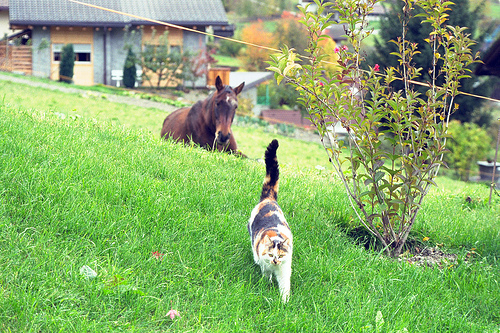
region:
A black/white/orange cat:
[245, 135, 300, 305]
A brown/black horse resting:
[155, 75, 250, 160]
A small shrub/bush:
[297, 30, 472, 260]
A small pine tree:
[115, 42, 140, 83]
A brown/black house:
[6, 0, 232, 85]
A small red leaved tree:
[182, 31, 212, 81]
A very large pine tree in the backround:
[351, 1, 496, 122]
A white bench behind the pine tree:
[107, 65, 138, 85]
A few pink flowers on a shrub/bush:
[330, 40, 385, 86]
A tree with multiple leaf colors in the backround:
[240, 10, 343, 78]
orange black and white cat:
[237, 123, 314, 295]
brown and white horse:
[156, 70, 260, 169]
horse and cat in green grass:
[138, 43, 303, 305]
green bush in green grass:
[300, 8, 460, 266]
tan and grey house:
[15, 5, 231, 98]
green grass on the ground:
[36, 165, 201, 315]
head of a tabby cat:
[256, 215, 297, 275]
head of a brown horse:
[205, 61, 251, 141]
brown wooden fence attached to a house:
[1, 40, 41, 86]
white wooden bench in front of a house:
[95, 55, 160, 96]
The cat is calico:
[231, 179, 306, 279]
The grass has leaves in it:
[46, 220, 148, 308]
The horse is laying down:
[165, 79, 280, 148]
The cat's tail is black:
[249, 135, 292, 199]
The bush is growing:
[305, 199, 442, 282]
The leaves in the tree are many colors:
[234, 15, 342, 95]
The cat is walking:
[239, 221, 311, 306]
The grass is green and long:
[48, 294, 110, 331]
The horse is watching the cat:
[195, 68, 255, 161]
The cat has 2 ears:
[251, 232, 295, 254]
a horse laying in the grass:
[160, 74, 247, 160]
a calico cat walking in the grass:
[249, 138, 292, 306]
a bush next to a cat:
[306, 0, 471, 246]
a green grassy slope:
[0, 80, 497, 326]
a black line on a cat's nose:
[270, 252, 276, 262]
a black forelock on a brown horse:
[216, 81, 228, 92]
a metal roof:
[5, 0, 225, 21]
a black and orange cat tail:
[260, 135, 280, 195]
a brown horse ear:
[211, 71, 221, 86]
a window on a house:
[49, 40, 92, 62]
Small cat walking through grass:
[245, 180, 295, 305]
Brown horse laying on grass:
[157, 60, 246, 161]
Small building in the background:
[28, 12, 248, 107]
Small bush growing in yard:
[323, 32, 435, 253]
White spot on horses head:
[224, 91, 231, 106]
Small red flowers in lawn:
[152, 239, 173, 270]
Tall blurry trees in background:
[225, 15, 497, 133]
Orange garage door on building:
[45, 34, 97, 84]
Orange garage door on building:
[140, 21, 186, 84]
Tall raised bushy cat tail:
[246, 133, 293, 188]